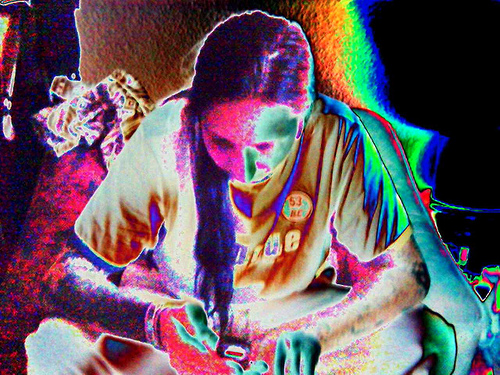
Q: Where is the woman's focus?
A: Her hands.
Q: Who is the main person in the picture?
A: A woman.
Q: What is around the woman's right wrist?
A: A wristband.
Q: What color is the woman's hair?
A: Brown.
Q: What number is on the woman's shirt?
A: 53.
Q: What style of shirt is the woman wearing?
A: T-shirt.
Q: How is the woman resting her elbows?
A: On her knees.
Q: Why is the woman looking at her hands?
A: There is an electronic.